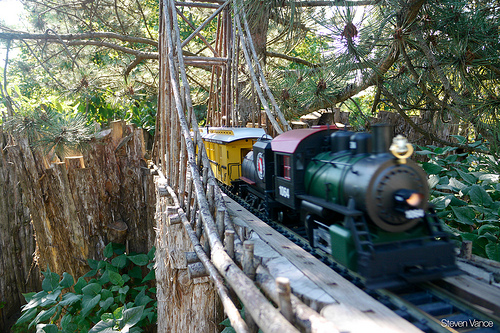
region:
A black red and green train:
[267, 128, 466, 304]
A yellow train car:
[202, 106, 264, 181]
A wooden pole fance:
[204, 240, 291, 328]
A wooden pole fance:
[152, 59, 207, 325]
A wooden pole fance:
[59, 108, 163, 275]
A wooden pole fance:
[2, 127, 68, 312]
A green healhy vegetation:
[34, 278, 102, 327]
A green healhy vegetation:
[474, 190, 499, 256]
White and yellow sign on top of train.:
[61, 311, 101, 322]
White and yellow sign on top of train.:
[422, 256, 486, 263]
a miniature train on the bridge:
[147, 78, 444, 303]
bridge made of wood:
[142, 57, 322, 315]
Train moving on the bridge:
[178, 118, 462, 284]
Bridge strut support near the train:
[147, 3, 244, 280]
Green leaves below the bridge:
[10, 240, 158, 332]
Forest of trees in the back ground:
[0, 0, 499, 133]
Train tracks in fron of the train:
[372, 275, 499, 331]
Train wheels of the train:
[232, 188, 314, 238]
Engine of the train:
[303, 151, 433, 234]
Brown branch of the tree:
[2, 28, 216, 71]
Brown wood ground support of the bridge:
[152, 185, 220, 332]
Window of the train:
[272, 153, 295, 183]